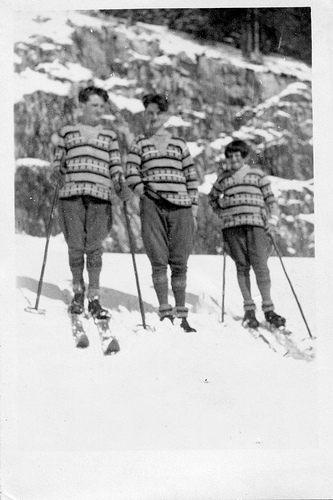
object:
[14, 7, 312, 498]
snow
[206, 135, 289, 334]
woman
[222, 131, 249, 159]
hair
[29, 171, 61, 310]
pole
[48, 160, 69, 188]
hand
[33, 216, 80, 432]
right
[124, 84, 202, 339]
man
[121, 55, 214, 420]
middle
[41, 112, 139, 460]
left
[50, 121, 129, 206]
pocket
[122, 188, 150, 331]
poles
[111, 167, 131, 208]
hands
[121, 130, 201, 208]
sweater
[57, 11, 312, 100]
slope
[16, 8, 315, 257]
cliff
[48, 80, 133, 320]
skis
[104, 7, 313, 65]
tree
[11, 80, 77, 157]
rock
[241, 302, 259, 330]
boots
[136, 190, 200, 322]
pants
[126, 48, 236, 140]
stone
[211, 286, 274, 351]
ski